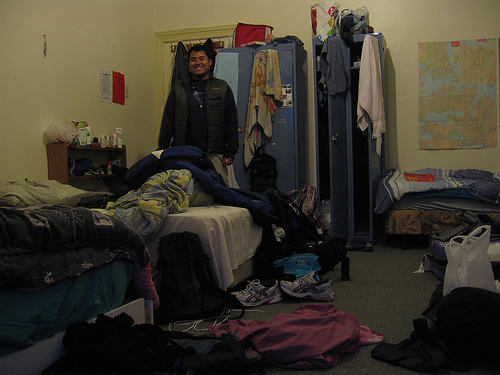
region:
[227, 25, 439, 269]
a parttion with clothes hanging on it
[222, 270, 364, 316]
a pair of tennis shoes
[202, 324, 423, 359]
a red shirt on ground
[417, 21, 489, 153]
a map on the wall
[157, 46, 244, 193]
a man smiling in a room that is messy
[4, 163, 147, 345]
a bed in the messy room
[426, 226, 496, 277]
a plastic bag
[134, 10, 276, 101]
a yellow door behind the man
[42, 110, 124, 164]
items on a shelve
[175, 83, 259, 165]
a black jacket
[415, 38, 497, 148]
map hanging on a wall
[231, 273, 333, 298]
pair of running shoes on the floor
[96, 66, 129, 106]
white paper and red paper hanging on the wall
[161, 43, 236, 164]
man wearing a black vest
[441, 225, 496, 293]
white plastic sack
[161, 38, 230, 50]
hooks hanging on the back of a door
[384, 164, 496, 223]
an unmade bed with a blue and white comforter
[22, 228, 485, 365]
cluttered floor of a bedroom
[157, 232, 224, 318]
backpack sitting on the floor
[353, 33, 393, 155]
white towel hanging over a locker door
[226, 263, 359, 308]
A pair of white shoes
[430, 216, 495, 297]
A white plastic bag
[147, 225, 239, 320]
A black backpack on the floor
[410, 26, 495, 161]
A map on the wall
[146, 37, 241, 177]
A man in a green vest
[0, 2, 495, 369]
A very dirty room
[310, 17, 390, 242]
An open blue locker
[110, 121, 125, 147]
A tube on a brown shelf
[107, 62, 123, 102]
A red paper on the wall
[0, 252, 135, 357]
A blue sofa top/blanket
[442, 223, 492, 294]
A bag in a room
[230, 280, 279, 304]
An athletic shoe on the ground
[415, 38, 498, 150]
A map of the world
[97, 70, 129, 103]
A pair of papers on a wall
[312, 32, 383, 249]
A blue locker in a room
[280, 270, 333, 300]
An Asics athletic shoe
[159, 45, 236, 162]
A man wearing a black shirt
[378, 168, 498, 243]
A bed with a book on it and a comforter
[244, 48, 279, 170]
A piece of clothing on a locker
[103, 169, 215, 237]
A yellow and blue blanket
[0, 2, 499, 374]
slightly messy room w/ a map on its wall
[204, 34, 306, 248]
twin blue lockers w/ a sticker of some sort on them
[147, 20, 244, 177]
a doorway that looks impossible to pass through cos of all the junk in front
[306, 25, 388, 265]
another pair of twin blue lockers, this time w/ opened doors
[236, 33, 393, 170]
several towels, or maybe sweaters, just hanging around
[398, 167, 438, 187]
a red book w/ yellow lettering atop something that might be a blanket atop something that might be a mattress w/ a steel blue sheet on it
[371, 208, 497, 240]
a box spring, i think. w/ a floral pattern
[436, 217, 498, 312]
a white plastic bag w/ a white plastic bag in it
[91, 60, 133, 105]
two flyers, or lists, on red paper, on white paper, beside a light switch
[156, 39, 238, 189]
the happy perpetrator